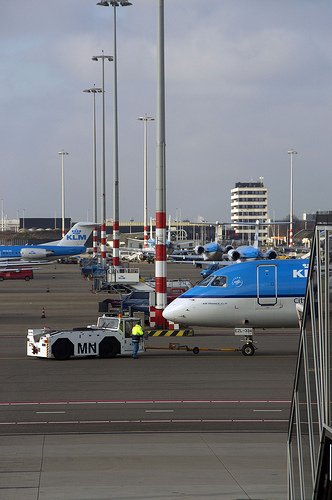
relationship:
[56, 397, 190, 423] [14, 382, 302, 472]
lines on runway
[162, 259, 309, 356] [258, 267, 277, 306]
airplane has door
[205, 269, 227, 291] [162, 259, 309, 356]
windshield on airplane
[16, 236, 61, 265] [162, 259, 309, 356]
booster on airplane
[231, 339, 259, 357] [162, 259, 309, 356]
wheel on airplane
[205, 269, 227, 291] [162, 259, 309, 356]
window on airplane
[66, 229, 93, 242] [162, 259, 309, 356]
logo on airplane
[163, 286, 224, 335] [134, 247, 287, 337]
nose of airplane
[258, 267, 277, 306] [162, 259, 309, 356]
door on airplane